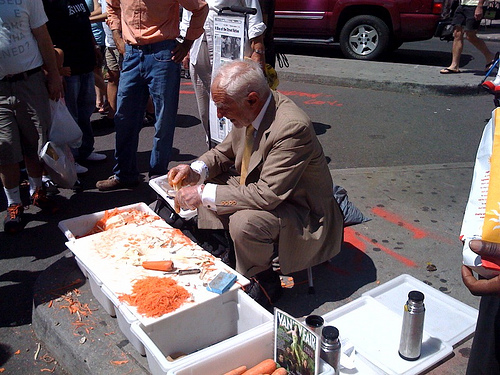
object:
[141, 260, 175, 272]
carrot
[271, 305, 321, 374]
magazine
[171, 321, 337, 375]
box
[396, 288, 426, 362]
thermo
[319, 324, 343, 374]
thermo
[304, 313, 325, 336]
thermo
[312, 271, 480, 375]
board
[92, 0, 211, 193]
spectator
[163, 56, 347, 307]
man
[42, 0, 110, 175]
spectator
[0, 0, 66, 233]
spectator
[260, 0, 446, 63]
vehicle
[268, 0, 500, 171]
background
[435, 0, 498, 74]
woman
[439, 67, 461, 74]
flip flops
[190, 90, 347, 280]
suit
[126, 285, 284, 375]
boxes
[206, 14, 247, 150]
newspaper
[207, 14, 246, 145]
display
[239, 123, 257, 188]
tie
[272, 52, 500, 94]
sidewalk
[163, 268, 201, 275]
carrot peeler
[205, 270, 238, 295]
sponge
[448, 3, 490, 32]
shorts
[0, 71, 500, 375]
road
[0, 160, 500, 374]
sidewalk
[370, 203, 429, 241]
paint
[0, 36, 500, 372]
ground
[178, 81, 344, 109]
paint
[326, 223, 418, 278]
paint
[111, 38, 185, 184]
jeans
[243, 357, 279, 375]
carrot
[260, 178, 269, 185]
wrinkles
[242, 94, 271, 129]
neck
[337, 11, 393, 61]
wheel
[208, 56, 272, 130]
head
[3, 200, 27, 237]
sneaker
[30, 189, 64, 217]
sneaker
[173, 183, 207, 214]
hand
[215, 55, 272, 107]
hair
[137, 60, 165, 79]
section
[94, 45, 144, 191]
leg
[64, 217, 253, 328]
cutting board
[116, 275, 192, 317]
carrot